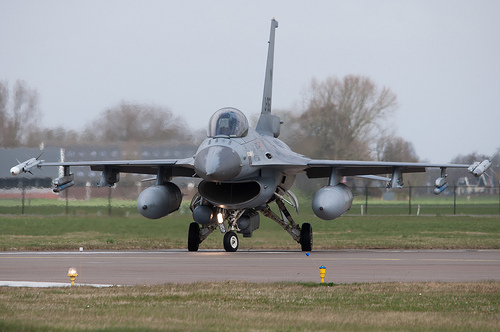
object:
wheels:
[185, 221, 203, 253]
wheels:
[220, 229, 240, 252]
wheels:
[298, 221, 315, 253]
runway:
[0, 248, 499, 289]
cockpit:
[206, 105, 250, 141]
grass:
[0, 280, 499, 332]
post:
[318, 265, 326, 282]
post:
[63, 265, 81, 285]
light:
[318, 262, 326, 272]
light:
[65, 265, 77, 274]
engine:
[134, 182, 190, 221]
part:
[252, 18, 284, 137]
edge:
[307, 161, 473, 169]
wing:
[253, 154, 499, 173]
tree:
[75, 98, 199, 146]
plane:
[9, 14, 492, 253]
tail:
[254, 17, 285, 140]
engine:
[309, 182, 355, 221]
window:
[206, 107, 247, 140]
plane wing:
[7, 156, 194, 178]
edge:
[37, 160, 180, 166]